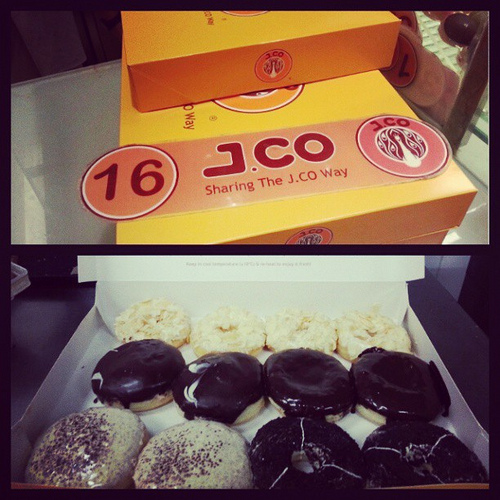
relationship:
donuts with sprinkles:
[20, 409, 254, 489] [43, 417, 105, 479]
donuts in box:
[26, 301, 478, 489] [119, 17, 467, 244]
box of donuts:
[8, 255, 491, 489] [26, 301, 478, 489]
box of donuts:
[119, 17, 467, 244] [26, 301, 478, 489]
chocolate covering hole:
[180, 353, 263, 420] [210, 364, 235, 383]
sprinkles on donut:
[43, 417, 105, 479] [29, 406, 148, 486]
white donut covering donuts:
[118, 301, 190, 345] [116, 298, 416, 359]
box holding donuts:
[8, 255, 491, 489] [26, 301, 478, 489]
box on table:
[119, 17, 467, 244] [11, 56, 489, 246]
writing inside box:
[184, 259, 315, 270] [8, 255, 491, 489]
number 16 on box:
[90, 157, 165, 203] [119, 17, 467, 244]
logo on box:
[365, 117, 432, 165] [119, 17, 467, 244]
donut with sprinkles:
[29, 406, 148, 486] [43, 417, 105, 479]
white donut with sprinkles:
[134, 422, 252, 489] [152, 440, 209, 489]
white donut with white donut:
[118, 301, 190, 345] [118, 301, 190, 345]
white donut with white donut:
[193, 311, 264, 359] [191, 305, 266, 356]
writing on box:
[184, 259, 315, 270] [8, 255, 491, 489]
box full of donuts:
[8, 255, 491, 489] [26, 301, 478, 489]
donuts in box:
[116, 298, 416, 359] [8, 255, 491, 489]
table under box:
[11, 56, 489, 246] [119, 17, 467, 244]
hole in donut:
[293, 448, 323, 472] [254, 416, 363, 489]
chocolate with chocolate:
[172, 352, 264, 426] [180, 353, 263, 420]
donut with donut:
[265, 347, 356, 420] [263, 347, 355, 421]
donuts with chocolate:
[88, 343, 436, 420] [180, 353, 263, 420]